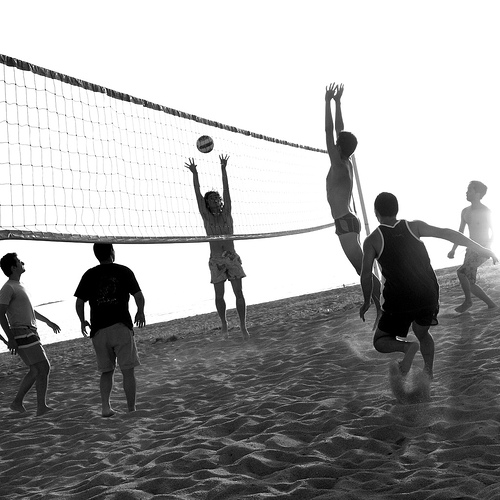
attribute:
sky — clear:
[240, 11, 260, 38]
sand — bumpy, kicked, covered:
[190, 377, 265, 441]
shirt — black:
[401, 264, 432, 280]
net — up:
[45, 55, 121, 207]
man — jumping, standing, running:
[315, 114, 361, 273]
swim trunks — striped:
[205, 262, 228, 271]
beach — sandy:
[268, 394, 328, 476]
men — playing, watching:
[204, 185, 479, 340]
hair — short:
[345, 136, 359, 148]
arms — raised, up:
[169, 157, 234, 184]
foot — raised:
[340, 290, 373, 322]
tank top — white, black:
[386, 219, 407, 228]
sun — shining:
[84, 12, 92, 15]